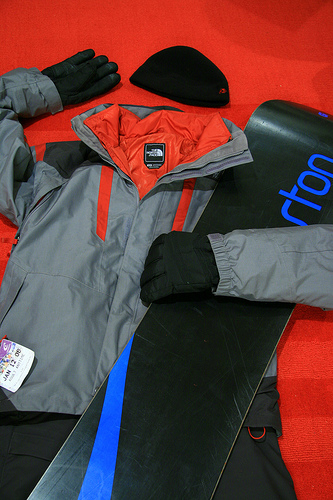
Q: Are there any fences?
A: No, there are no fences.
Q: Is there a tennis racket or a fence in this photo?
A: No, there are no fences or rackets.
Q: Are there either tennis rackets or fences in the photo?
A: No, there are no fences or tennis rackets.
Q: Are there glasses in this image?
A: No, there are no glasses.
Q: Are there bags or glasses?
A: No, there are no glasses or bags.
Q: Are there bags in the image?
A: No, there are no bags.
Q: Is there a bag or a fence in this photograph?
A: No, there are no bags or fences.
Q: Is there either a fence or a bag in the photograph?
A: No, there are no bags or fences.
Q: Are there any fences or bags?
A: No, there are no bags or fences.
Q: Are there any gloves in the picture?
A: Yes, there are gloves.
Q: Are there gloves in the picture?
A: Yes, there are gloves.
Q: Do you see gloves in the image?
A: Yes, there are gloves.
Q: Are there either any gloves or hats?
A: Yes, there are gloves.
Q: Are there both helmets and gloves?
A: No, there are gloves but no helmets.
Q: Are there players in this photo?
A: No, there are no players.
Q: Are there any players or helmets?
A: No, there are no players or helmets.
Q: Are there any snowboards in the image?
A: Yes, there is a snowboard.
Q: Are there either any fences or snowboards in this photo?
A: Yes, there is a snowboard.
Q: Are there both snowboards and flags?
A: No, there is a snowboard but no flags.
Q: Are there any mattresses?
A: No, there are no mattresses.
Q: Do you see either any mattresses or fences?
A: No, there are no mattresses or fences.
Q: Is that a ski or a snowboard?
A: That is a snowboard.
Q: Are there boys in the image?
A: No, there are no boys.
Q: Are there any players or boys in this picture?
A: No, there are no boys or players.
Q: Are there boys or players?
A: No, there are no boys or players.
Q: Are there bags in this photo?
A: No, there are no bags.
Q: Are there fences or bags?
A: No, there are no bags or fences.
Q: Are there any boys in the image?
A: No, there are no boys.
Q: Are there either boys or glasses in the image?
A: No, there are no boys or glasses.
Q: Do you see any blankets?
A: Yes, there is a blanket.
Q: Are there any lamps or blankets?
A: Yes, there is a blanket.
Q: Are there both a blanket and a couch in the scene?
A: No, there is a blanket but no couches.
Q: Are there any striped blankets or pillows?
A: Yes, there is a striped blanket.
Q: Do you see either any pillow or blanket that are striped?
A: Yes, the blanket is striped.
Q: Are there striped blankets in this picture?
A: Yes, there is a striped blanket.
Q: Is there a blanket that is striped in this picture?
A: Yes, there is a striped blanket.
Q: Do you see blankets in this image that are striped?
A: Yes, there is a blanket that is striped.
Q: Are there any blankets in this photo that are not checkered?
A: Yes, there is a striped blanket.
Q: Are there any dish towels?
A: No, there are no dish towels.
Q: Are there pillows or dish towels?
A: No, there are no dish towels or pillows.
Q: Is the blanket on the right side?
A: Yes, the blanket is on the right of the image.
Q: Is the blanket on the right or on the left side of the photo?
A: The blanket is on the right of the image.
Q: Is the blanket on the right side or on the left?
A: The blanket is on the right of the image.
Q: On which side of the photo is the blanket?
A: The blanket is on the right of the image.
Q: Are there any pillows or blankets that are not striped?
A: No, there is a blanket but it is striped.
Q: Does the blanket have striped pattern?
A: Yes, the blanket is striped.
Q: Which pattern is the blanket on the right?
A: The blanket is striped.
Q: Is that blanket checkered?
A: No, the blanket is striped.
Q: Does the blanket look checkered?
A: No, the blanket is striped.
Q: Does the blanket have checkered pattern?
A: No, the blanket is striped.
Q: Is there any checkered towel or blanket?
A: No, there is a blanket but it is striped.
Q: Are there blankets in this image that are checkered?
A: No, there is a blanket but it is striped.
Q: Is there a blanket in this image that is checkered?
A: No, there is a blanket but it is striped.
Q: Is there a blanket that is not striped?
A: No, there is a blanket but it is striped.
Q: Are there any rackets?
A: No, there are no rackets.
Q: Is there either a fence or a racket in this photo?
A: No, there are no rackets or fences.